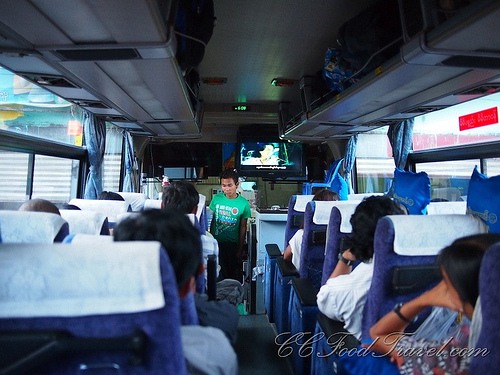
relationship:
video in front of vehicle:
[240, 141, 289, 165] [131, 134, 334, 202]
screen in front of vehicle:
[240, 141, 289, 165] [131, 134, 334, 202]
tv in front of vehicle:
[240, 141, 289, 165] [131, 134, 334, 202]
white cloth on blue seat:
[3, 249, 164, 314] [1, 252, 194, 375]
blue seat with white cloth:
[363, 223, 478, 334] [388, 217, 487, 250]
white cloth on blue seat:
[313, 205, 339, 221] [303, 202, 327, 272]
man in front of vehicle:
[212, 168, 246, 258] [131, 134, 334, 202]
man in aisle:
[212, 168, 246, 258] [198, 239, 296, 369]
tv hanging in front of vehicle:
[240, 141, 289, 165] [131, 134, 334, 202]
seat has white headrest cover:
[1, 252, 194, 375] [3, 249, 164, 314]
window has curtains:
[2, 150, 81, 205] [83, 117, 108, 197]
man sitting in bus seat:
[124, 214, 219, 361] [1, 252, 194, 375]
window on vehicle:
[2, 150, 81, 205] [3, 4, 498, 375]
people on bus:
[290, 206, 472, 351] [3, 4, 498, 375]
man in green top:
[212, 168, 246, 258] [209, 196, 247, 245]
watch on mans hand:
[337, 252, 353, 265] [329, 241, 372, 282]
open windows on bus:
[3, 71, 116, 195] [3, 4, 498, 375]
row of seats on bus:
[276, 194, 497, 363] [3, 4, 498, 375]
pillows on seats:
[390, 174, 437, 205] [327, 199, 399, 249]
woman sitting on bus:
[387, 236, 475, 374] [3, 4, 498, 375]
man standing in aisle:
[212, 168, 246, 258] [198, 239, 296, 369]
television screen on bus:
[240, 141, 289, 165] [3, 4, 498, 375]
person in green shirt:
[212, 168, 246, 258] [209, 196, 247, 245]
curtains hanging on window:
[83, 117, 108, 197] [2, 150, 81, 205]